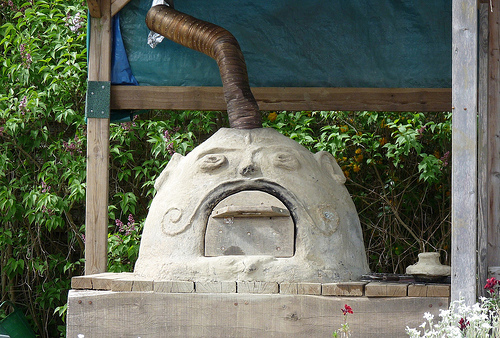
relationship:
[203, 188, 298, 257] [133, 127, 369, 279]
door on furnace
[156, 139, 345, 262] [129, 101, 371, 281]
face on oven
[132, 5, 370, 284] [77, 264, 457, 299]
furnace sits on table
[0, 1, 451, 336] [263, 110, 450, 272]
foliage in trees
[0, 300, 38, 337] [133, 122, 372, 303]
bucket left of oven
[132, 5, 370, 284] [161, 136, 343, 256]
furnace with face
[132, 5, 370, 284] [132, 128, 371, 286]
furnace shaped like a head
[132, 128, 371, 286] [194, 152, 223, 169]
head has eye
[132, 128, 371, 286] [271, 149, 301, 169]
head has eye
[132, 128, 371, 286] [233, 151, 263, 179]
head has nose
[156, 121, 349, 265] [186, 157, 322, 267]
head has mouth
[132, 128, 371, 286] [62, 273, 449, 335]
head on shelf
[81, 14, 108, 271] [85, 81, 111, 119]
post wit bracket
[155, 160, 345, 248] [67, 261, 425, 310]
oven sits on boards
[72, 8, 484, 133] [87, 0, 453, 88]
blue tarp on blue tarp